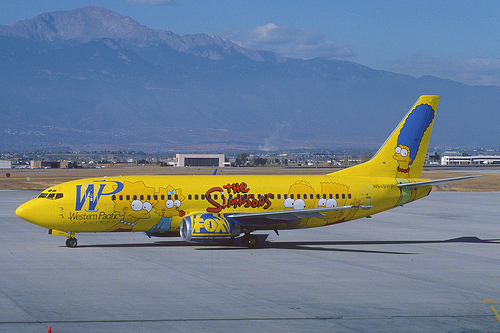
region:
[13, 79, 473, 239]
yellow plane with the simpsons painted on it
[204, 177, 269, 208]
red lettering on yellow plane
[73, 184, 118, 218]
blue lettering on the plane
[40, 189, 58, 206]
windows of the cockpit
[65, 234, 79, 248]
front wheels on the airplane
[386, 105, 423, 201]
marge simpson painted on the plane's tail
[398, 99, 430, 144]
blue paint on a plane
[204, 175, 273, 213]
red letters on a plane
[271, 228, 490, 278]
a shadow of a plane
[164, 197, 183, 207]
two white eyes on plane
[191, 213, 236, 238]
the word fox on a plane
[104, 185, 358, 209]
a row of windows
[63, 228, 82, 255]
front wheels on plane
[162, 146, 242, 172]
a large building in background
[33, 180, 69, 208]
the front windows of the plane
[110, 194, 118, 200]
small window on plane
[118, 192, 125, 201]
small window on plane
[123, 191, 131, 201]
small window on plane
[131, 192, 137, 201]
small window on plane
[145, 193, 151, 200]
small window on plane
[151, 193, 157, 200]
small window on plane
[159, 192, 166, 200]
small window on plane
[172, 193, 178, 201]
small window on plane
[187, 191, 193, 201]
small window on plane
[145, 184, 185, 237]
Maggie Simpson on a plane.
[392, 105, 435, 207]
Marge Simpson on the back of a plane with long blue hair.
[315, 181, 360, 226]
Bart Simpson on a plane waving.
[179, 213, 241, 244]
Blue, yellow and silver engine that says FOX on it.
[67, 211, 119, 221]
Black words Western Pacific by Lisa Simpson on a plane.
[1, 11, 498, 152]
Mountain range that looks blue.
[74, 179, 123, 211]
Large blue WP on a plane side.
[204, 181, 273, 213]
The Simpsons in red letters.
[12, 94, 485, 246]
A long yellow Simpsons plane with characters on the side.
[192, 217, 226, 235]
Yellow word FOX.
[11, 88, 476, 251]
The plane has the Simpsons on it.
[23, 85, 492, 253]
The plane is yellow.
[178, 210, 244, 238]
The engine says Fox.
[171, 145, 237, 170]
There are buildings in the background.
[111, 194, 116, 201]
air plane has a window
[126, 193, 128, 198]
air plane has a window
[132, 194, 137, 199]
air plane has a window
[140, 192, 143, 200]
air plane has a window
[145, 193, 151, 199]
air plane has a window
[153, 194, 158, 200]
air plane has a window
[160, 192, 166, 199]
air plane has a window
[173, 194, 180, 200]
air plane has a window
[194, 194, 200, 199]
air plane has a window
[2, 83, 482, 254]
An airplane is yellow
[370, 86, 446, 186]
Marge Simpson on the tail of a plane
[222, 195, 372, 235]
The wing of an airplane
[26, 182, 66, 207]
Front windows of a plane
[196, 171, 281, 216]
"THE SIMPSONS" written on plane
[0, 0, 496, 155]
Mountain range in the distance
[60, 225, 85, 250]
Black wheels of an airplane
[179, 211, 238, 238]
"FOX" written on airplane